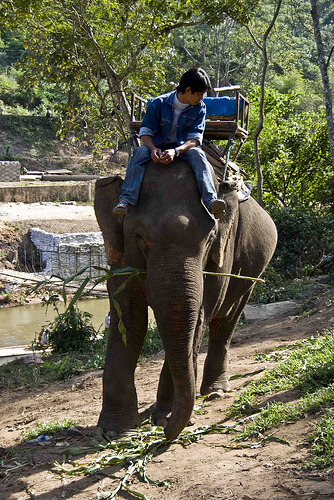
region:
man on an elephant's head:
[127, 67, 226, 212]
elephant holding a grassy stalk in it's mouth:
[30, 266, 270, 332]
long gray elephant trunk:
[144, 254, 200, 441]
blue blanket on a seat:
[202, 96, 241, 116]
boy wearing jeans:
[119, 141, 221, 206]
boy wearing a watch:
[171, 148, 180, 154]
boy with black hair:
[172, 63, 213, 104]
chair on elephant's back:
[126, 76, 251, 178]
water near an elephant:
[1, 286, 167, 350]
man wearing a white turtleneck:
[171, 91, 189, 148]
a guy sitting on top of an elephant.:
[92, 67, 277, 440]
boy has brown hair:
[160, 62, 207, 99]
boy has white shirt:
[143, 92, 185, 134]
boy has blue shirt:
[154, 96, 202, 142]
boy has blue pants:
[136, 140, 205, 199]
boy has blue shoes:
[102, 185, 133, 218]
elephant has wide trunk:
[154, 243, 199, 438]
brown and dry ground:
[162, 449, 281, 494]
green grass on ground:
[269, 321, 331, 461]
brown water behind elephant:
[1, 299, 94, 341]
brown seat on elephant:
[130, 84, 239, 162]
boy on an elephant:
[126, 53, 261, 272]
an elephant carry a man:
[73, 55, 289, 455]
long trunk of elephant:
[146, 255, 211, 447]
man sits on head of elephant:
[104, 62, 237, 232]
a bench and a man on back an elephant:
[104, 53, 256, 223]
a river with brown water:
[2, 270, 108, 350]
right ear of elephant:
[217, 183, 243, 265]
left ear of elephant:
[83, 170, 128, 262]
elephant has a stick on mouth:
[35, 209, 269, 353]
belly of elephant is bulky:
[204, 189, 281, 324]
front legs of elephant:
[93, 297, 202, 443]